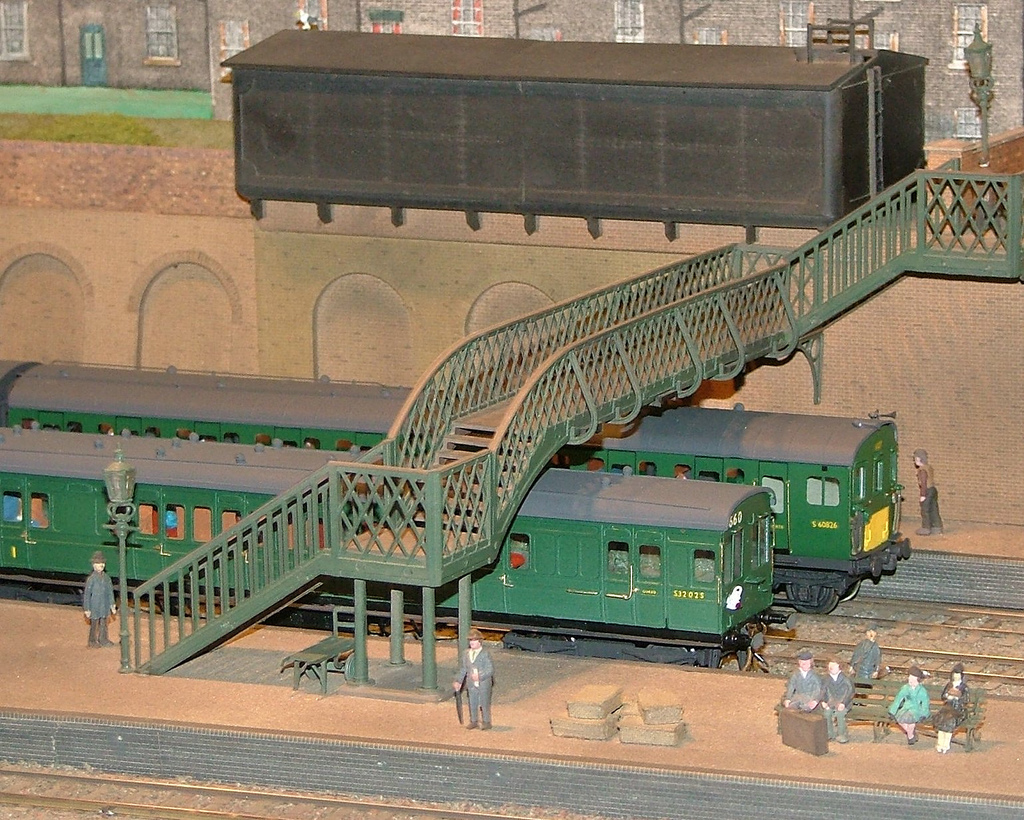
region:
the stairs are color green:
[65, 131, 1020, 682]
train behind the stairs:
[3, 425, 785, 669]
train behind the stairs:
[21, 357, 906, 509]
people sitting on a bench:
[768, 643, 993, 800]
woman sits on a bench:
[882, 656, 934, 756]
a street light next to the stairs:
[91, 425, 164, 685]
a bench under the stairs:
[274, 537, 393, 702]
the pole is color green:
[337, 573, 379, 694]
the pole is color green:
[371, 576, 410, 660]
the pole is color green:
[415, 580, 435, 705]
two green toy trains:
[51, 366, 852, 667]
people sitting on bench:
[778, 638, 972, 737]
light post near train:
[78, 440, 161, 685]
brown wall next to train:
[315, 224, 1008, 539]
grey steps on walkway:
[430, 402, 529, 540]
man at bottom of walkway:
[76, 557, 141, 674]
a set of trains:
[8, 325, 932, 743]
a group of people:
[744, 601, 992, 779]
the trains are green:
[8, 329, 963, 700]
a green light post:
[84, 423, 168, 699]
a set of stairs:
[89, 72, 1020, 696]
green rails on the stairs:
[57, 119, 1015, 689]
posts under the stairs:
[299, 549, 493, 720]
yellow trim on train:
[827, 481, 932, 574]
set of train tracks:
[787, 549, 1022, 739]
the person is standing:
[78, 557, 120, 638]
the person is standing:
[447, 628, 514, 742]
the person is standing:
[779, 632, 821, 751]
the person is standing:
[845, 632, 872, 705]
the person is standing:
[892, 676, 919, 753]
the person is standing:
[937, 661, 982, 761]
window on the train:
[693, 557, 728, 603]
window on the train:
[633, 541, 679, 583]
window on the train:
[498, 524, 527, 576]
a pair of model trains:
[42, 328, 975, 741]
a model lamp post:
[76, 443, 175, 653]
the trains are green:
[13, 332, 955, 696]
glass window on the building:
[138, 27, 171, 65]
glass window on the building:
[140, 8, 175, 29]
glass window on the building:
[462, 0, 479, 33]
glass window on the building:
[620, 0, 639, 36]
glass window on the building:
[782, 24, 808, 45]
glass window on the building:
[950, 33, 982, 71]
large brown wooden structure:
[232, 22, 850, 216]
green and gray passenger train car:
[517, 478, 777, 644]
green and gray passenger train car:
[0, 421, 263, 548]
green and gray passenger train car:
[725, 394, 922, 584]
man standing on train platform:
[73, 550, 115, 650]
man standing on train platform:
[770, 654, 840, 747]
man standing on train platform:
[845, 619, 881, 668]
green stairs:
[437, 259, 741, 415]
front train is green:
[3, 410, 803, 689]